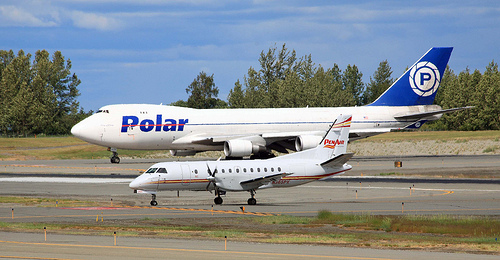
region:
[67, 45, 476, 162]
a white and blue jet airplane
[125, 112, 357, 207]
a white and orange striped airplane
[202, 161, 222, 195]
an airplane propellor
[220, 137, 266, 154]
an airplane jet engine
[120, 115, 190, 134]
blue Polar painted logo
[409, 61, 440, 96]
blue Polar painted logo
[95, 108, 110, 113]
several airplane cockpit windows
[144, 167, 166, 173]
several airplane cockpit windows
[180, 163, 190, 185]
an airplane door hatch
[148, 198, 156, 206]
an airplane front landing gear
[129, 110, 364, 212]
Plane on the ground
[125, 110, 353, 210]
Plane is on the ground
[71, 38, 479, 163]
Airplane on the ground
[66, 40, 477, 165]
Airplane is on the ground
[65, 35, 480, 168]
Plane on a runway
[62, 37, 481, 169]
Plane is on a runway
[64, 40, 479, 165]
Airplane on a runway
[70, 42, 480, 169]
Airplane is on a runway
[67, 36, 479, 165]
Blue and white airplane on a runway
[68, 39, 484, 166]
Blue and white plane on a runway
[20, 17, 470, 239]
this is at an airport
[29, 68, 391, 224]
this is a runway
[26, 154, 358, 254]
this is an air strip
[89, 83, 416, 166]
this is an airplane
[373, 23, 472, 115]
the tail is blue and white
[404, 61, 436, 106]
the letter on the tail is P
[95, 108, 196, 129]
the plane says "polar"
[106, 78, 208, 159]
the writing is red and blue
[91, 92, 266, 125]
this is a cargo plane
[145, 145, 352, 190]
this is a commuter jet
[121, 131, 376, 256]
a plane on the ground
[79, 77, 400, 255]
an airplane on the ground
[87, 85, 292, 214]
a large plane on the ground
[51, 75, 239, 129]
a large airplane on the ground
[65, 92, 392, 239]
a white plane on the ground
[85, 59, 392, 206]
a white airplane on the ground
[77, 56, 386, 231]
a large white airplane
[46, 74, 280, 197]
a large passenger plane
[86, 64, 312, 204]
a large passenger airplane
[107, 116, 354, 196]
Small jet on a tarmac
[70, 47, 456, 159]
Large jet on a tarmac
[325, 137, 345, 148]
Red letters on a plane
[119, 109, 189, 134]
Blue letters on a plane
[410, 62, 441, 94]
White circle design on a plane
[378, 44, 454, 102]
Blue tail on a plane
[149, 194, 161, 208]
Front landing gear on a plane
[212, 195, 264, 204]
Back landing gear on a plane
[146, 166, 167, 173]
Cockpit window on a plane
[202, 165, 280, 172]
Long row of passenger windows